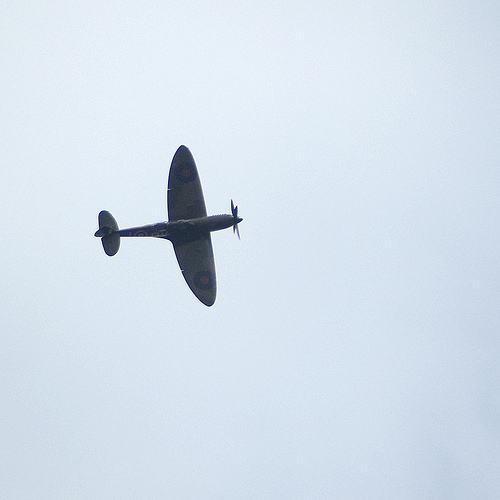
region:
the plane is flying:
[88, 156, 298, 303]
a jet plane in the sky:
[68, 129, 280, 351]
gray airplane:
[65, 132, 249, 311]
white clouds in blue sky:
[41, 37, 99, 92]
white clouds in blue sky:
[284, 30, 318, 110]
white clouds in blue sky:
[323, 234, 402, 353]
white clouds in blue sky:
[117, 396, 174, 435]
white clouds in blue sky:
[273, 354, 319, 412]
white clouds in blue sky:
[379, 269, 445, 345]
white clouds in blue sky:
[44, 329, 124, 390]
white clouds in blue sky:
[61, 57, 97, 110]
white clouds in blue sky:
[217, 37, 264, 84]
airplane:
[66, 143, 255, 319]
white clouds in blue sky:
[345, 281, 385, 341]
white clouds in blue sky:
[389, 340, 424, 415]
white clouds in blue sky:
[95, 321, 170, 369]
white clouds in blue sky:
[39, 353, 168, 457]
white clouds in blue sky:
[52, 56, 94, 90]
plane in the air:
[95, 111, 310, 277]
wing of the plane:
[170, 245, 235, 325]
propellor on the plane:
[205, 200, 260, 240]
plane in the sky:
[85, 150, 295, 310]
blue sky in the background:
[270, 280, 395, 375]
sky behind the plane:
[287, 46, 439, 181]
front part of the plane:
[212, 185, 271, 240]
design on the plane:
[188, 260, 225, 297]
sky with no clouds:
[326, 204, 429, 324]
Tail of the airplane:
[90, 207, 119, 257]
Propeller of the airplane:
[228, 197, 243, 239]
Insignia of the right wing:
[188, 266, 220, 293]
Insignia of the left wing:
[172, 156, 202, 186]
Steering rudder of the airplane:
[91, 222, 118, 241]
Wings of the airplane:
[161, 140, 225, 320]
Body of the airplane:
[118, 209, 235, 241]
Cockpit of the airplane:
[158, 216, 195, 236]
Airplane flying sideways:
[93, 141, 248, 308]